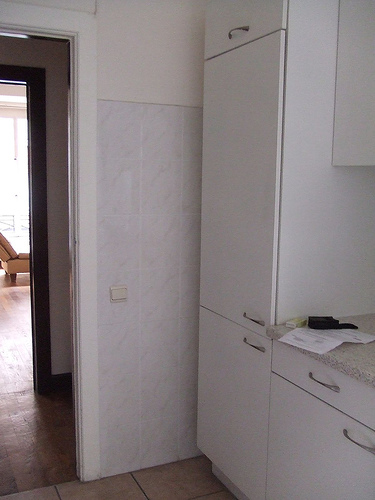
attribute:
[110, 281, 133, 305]
switch — light, plastic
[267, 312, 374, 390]
counter — granite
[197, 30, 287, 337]
cabinet — large, white, tall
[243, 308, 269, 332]
handle — metal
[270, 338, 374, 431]
drawer — white, wide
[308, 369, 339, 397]
handle — metal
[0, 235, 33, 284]
couch — sofa, brown, reclining, chair, tan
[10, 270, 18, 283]
leg — wooden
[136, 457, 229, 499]
tile — square, ceramic, linoleum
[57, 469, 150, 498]
tile — square, ceramic, linoleum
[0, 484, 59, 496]
tile — square, ceramic, linoleum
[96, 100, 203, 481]
wall — white, tiled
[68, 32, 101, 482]
frame — white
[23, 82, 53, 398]
jamb — brown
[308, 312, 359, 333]
case — black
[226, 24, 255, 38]
handle — silver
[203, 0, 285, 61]
cabinet — white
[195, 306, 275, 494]
cabinet — white, plain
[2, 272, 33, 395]
flooring — hardwood, brown, wooden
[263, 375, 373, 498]
cabinet — white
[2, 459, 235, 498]
floor — tiled, beige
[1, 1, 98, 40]
frame — white